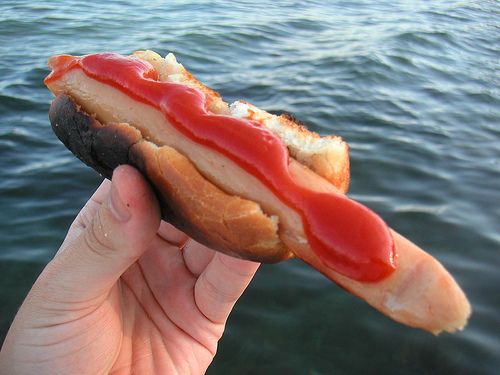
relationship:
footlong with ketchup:
[42, 49, 473, 337] [47, 53, 394, 284]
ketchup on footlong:
[47, 53, 394, 284] [42, 49, 473, 337]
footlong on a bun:
[42, 49, 473, 337] [48, 47, 351, 265]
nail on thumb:
[102, 174, 135, 226] [47, 160, 164, 304]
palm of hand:
[112, 257, 196, 375] [2, 169, 262, 372]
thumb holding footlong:
[47, 160, 164, 304] [42, 49, 473, 337]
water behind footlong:
[0, 0, 498, 370] [42, 49, 473, 337]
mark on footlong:
[383, 258, 437, 314] [42, 49, 473, 337]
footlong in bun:
[42, 49, 473, 337] [48, 47, 351, 265]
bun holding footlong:
[48, 47, 351, 265] [42, 49, 473, 337]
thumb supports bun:
[47, 160, 164, 304] [48, 47, 351, 265]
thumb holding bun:
[47, 160, 164, 304] [48, 47, 351, 265]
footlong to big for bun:
[42, 49, 473, 337] [48, 47, 351, 265]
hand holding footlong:
[2, 169, 262, 372] [42, 49, 473, 337]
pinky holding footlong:
[193, 250, 266, 328] [42, 49, 473, 337]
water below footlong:
[0, 0, 498, 370] [42, 49, 473, 337]